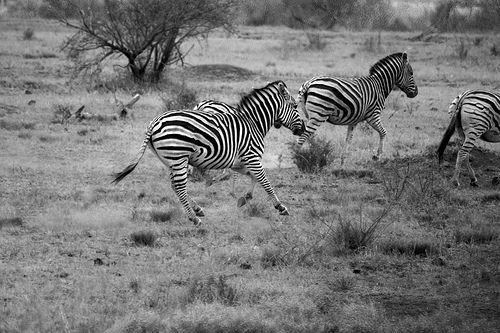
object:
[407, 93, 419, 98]
mouth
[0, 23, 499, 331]
ground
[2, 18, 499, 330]
grass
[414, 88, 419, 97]
front snout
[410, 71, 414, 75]
eye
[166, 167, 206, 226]
back legs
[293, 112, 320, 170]
back legs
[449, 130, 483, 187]
back legs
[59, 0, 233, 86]
tree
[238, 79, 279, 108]
hair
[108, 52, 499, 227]
group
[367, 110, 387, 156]
leg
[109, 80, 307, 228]
zebras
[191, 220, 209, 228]
feet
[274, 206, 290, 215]
feet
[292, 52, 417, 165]
zebra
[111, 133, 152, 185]
tail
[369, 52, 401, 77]
mane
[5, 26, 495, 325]
field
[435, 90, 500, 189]
zebra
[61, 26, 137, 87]
tree branches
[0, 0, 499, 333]
jungle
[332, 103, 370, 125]
stomach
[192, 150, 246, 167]
stomach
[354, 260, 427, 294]
bad sentence